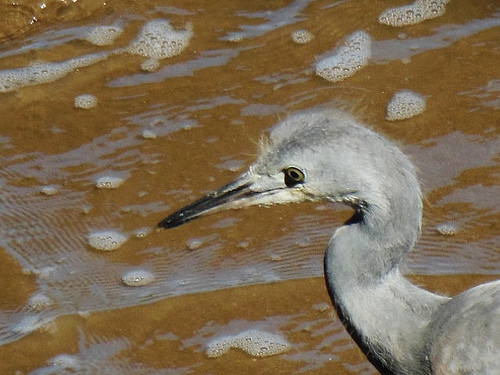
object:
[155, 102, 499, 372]
bird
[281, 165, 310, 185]
eye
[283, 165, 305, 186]
eye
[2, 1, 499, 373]
beach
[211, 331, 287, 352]
foam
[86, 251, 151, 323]
beach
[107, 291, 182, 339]
beach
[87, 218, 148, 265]
foam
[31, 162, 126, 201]
foam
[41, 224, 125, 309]
beach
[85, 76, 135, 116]
beach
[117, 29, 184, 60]
foam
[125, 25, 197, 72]
foam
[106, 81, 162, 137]
beach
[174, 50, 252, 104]
beach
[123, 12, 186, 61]
foam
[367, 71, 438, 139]
foam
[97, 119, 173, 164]
beach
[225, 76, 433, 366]
bird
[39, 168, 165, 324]
water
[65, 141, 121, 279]
bubbles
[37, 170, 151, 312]
surface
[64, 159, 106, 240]
sand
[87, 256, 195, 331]
water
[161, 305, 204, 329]
water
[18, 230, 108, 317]
lines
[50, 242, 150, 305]
grids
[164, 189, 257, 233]
beak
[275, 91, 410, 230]
feathers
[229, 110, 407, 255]
head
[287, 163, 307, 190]
eye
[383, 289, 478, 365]
markings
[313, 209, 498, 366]
body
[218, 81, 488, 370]
bird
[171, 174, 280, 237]
beak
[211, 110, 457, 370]
bird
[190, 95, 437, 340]
fowl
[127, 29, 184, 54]
bubbles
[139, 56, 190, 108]
water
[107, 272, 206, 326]
water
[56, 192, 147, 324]
river bed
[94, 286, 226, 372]
river bed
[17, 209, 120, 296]
pattern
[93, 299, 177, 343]
water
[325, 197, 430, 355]
neck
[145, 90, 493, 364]
bird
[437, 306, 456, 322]
gray